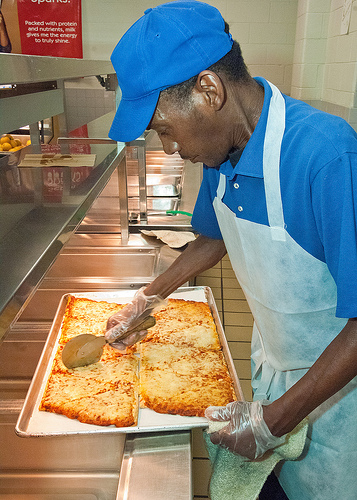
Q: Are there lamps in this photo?
A: No, there are no lamps.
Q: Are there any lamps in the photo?
A: No, there are no lamps.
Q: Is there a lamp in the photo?
A: No, there are no lamps.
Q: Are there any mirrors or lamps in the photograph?
A: No, there are no lamps or mirrors.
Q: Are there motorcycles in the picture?
A: No, there are no motorcycles.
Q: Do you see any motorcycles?
A: No, there are no motorcycles.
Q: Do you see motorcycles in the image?
A: No, there are no motorcycles.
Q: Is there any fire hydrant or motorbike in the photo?
A: No, there are no motorcycles or fire hydrants.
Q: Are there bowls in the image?
A: No, there are no bowls.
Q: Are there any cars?
A: No, there are no cars.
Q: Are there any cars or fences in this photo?
A: No, there are no cars or fences.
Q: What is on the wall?
A: The sign is on the wall.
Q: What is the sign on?
A: The sign is on the wall.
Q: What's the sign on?
A: The sign is on the wall.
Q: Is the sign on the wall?
A: Yes, the sign is on the wall.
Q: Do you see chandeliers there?
A: No, there are no chandeliers.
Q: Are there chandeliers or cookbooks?
A: No, there are no chandeliers or cookbooks.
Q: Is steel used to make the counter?
A: Yes, the counter is made of steel.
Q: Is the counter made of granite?
A: No, the counter is made of steel.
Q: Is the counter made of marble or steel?
A: The counter is made of steel.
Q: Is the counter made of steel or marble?
A: The counter is made of steel.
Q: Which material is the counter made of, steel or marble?
A: The counter is made of steel.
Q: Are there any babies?
A: No, there are no babies.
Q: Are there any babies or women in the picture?
A: No, there are no babies or women.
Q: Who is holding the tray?
A: The man is holding the tray.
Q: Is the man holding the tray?
A: Yes, the man is holding the tray.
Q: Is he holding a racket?
A: No, the man is holding the tray.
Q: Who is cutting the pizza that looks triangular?
A: The man is cutting the pizza.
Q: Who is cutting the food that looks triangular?
A: The man is cutting the pizza.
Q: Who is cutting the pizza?
A: The man is cutting the pizza.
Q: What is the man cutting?
A: The man is cutting the pizza.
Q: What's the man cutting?
A: The man is cutting the pizza.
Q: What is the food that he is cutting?
A: The food is a pizza.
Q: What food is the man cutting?
A: The man is cutting the pizza.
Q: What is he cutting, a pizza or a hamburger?
A: The man is cutting a pizza.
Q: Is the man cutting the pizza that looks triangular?
A: Yes, the man is cutting the pizza.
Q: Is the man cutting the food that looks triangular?
A: Yes, the man is cutting the pizza.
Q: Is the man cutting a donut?
A: No, the man is cutting the pizza.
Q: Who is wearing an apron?
A: The man is wearing an apron.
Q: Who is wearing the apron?
A: The man is wearing an apron.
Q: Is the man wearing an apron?
A: Yes, the man is wearing an apron.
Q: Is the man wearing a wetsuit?
A: No, the man is wearing an apron.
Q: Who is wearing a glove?
A: The man is wearing a glove.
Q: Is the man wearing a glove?
A: Yes, the man is wearing a glove.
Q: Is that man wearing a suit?
A: No, the man is wearing a glove.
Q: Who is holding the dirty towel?
A: The man is holding the towel.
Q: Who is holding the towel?
A: The man is holding the towel.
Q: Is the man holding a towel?
A: Yes, the man is holding a towel.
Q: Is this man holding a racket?
A: No, the man is holding a towel.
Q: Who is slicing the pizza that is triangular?
A: The man is slicing the pizza.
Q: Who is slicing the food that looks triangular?
A: The man is slicing the pizza.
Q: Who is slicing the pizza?
A: The man is slicing the pizza.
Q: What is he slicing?
A: The man is slicing the pizza.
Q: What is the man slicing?
A: The man is slicing the pizza.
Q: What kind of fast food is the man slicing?
A: The man is slicing the pizza.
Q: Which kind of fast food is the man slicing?
A: The man is slicing the pizza.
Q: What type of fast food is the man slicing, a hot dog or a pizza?
A: The man is slicing a pizza.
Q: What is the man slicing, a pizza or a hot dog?
A: The man is slicing a pizza.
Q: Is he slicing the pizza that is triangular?
A: Yes, the man is slicing the pizza.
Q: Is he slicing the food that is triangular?
A: Yes, the man is slicing the pizza.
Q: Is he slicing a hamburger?
A: No, the man is slicing the pizza.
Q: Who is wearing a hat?
A: The man is wearing a hat.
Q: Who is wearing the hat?
A: The man is wearing a hat.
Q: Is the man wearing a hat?
A: Yes, the man is wearing a hat.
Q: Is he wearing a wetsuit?
A: No, the man is wearing a hat.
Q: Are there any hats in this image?
A: Yes, there is a hat.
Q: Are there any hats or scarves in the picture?
A: Yes, there is a hat.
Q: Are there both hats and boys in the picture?
A: No, there is a hat but no boys.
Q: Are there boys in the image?
A: No, there are no boys.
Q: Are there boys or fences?
A: No, there are no boys or fences.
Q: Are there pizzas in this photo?
A: Yes, there is a pizza.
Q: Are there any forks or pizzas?
A: Yes, there is a pizza.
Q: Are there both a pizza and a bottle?
A: No, there is a pizza but no bottles.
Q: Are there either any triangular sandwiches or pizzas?
A: Yes, there is a triangular pizza.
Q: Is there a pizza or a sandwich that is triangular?
A: Yes, the pizza is triangular.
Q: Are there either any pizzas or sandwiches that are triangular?
A: Yes, the pizza is triangular.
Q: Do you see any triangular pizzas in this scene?
A: Yes, there is a triangular pizza.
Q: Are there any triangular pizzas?
A: Yes, there is a triangular pizza.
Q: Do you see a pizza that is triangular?
A: Yes, there is a triangular pizza.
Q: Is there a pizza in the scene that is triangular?
A: Yes, there is a pizza that is triangular.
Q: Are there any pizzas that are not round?
A: Yes, there is a triangular pizza.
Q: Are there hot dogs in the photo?
A: No, there are no hot dogs.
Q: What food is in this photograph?
A: The food is a pizza.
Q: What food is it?
A: The food is a pizza.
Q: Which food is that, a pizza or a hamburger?
A: That is a pizza.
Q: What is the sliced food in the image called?
A: The food is a pizza.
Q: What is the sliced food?
A: The food is a pizza.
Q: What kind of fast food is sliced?
A: The fast food is a pizza.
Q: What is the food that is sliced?
A: The food is a pizza.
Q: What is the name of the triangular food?
A: The food is a pizza.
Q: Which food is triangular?
A: The food is a pizza.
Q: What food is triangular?
A: The food is a pizza.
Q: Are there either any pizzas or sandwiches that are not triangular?
A: No, there is a pizza but it is triangular.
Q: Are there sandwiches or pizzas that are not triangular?
A: No, there is a pizza but it is triangular.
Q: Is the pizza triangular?
A: Yes, the pizza is triangular.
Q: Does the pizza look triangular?
A: Yes, the pizza is triangular.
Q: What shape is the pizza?
A: The pizza is triangular.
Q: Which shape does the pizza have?
A: The pizza has triangular shape.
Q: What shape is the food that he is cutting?
A: The pizza is triangular.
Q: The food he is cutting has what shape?
A: The pizza is triangular.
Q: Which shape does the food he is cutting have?
A: The pizza has triangular shape.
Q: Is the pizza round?
A: No, the pizza is triangular.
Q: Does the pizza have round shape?
A: No, the pizza is triangular.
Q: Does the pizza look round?
A: No, the pizza is triangular.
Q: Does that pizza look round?
A: No, the pizza is triangular.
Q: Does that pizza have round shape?
A: No, the pizza is triangular.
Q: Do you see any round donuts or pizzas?
A: No, there is a pizza but it is triangular.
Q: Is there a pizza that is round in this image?
A: No, there is a pizza but it is triangular.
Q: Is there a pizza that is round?
A: No, there is a pizza but it is triangular.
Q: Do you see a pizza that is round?
A: No, there is a pizza but it is triangular.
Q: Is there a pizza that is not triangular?
A: No, there is a pizza but it is triangular.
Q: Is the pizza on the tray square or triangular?
A: The pizza is triangular.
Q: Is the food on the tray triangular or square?
A: The pizza is triangular.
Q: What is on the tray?
A: The pizza is on the tray.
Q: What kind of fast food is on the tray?
A: The food is a pizza.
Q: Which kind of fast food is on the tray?
A: The food is a pizza.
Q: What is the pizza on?
A: The pizza is on the tray.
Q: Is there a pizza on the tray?
A: Yes, there is a pizza on the tray.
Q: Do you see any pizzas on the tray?
A: Yes, there is a pizza on the tray.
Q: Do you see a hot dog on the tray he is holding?
A: No, there is a pizza on the tray.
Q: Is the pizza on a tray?
A: Yes, the pizza is on a tray.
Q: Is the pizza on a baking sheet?
A: No, the pizza is on a tray.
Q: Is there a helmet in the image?
A: No, there are no helmets.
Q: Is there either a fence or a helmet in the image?
A: No, there are no helmets or fences.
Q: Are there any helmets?
A: No, there are no helmets.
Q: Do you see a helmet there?
A: No, there are no helmets.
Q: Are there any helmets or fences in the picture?
A: No, there are no helmets or fences.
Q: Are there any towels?
A: Yes, there is a towel.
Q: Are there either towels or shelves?
A: Yes, there is a towel.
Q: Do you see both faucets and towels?
A: No, there is a towel but no faucets.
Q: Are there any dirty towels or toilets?
A: Yes, there is a dirty towel.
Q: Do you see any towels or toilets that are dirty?
A: Yes, the towel is dirty.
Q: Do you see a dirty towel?
A: Yes, there is a dirty towel.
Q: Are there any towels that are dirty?
A: Yes, there is a dirty towel.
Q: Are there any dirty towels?
A: Yes, there is a dirty towel.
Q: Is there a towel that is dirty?
A: Yes, there is a towel that is dirty.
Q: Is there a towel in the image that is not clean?
A: Yes, there is a dirty towel.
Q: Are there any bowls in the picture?
A: No, there are no bowls.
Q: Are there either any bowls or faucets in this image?
A: No, there are no bowls or faucets.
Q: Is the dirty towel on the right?
A: Yes, the towel is on the right of the image.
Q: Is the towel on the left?
A: No, the towel is on the right of the image.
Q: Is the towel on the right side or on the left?
A: The towel is on the right of the image.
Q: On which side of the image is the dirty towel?
A: The towel is on the right of the image.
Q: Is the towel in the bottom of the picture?
A: Yes, the towel is in the bottom of the image.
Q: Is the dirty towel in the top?
A: No, the towel is in the bottom of the image.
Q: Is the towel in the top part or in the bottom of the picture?
A: The towel is in the bottom of the image.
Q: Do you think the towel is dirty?
A: Yes, the towel is dirty.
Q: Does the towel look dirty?
A: Yes, the towel is dirty.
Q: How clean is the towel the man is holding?
A: The towel is dirty.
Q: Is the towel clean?
A: No, the towel is dirty.